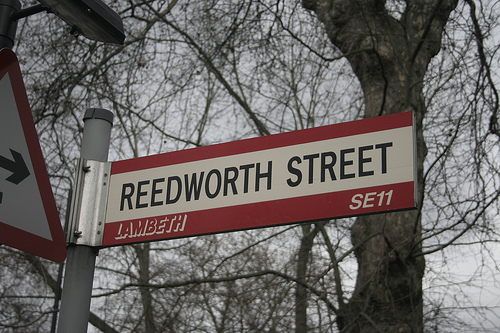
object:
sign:
[101, 110, 415, 247]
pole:
[58, 108, 113, 332]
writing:
[119, 142, 393, 212]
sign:
[0, 48, 66, 262]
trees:
[12, 15, 500, 324]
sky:
[0, 0, 498, 327]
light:
[1, 0, 126, 45]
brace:
[62, 158, 112, 249]